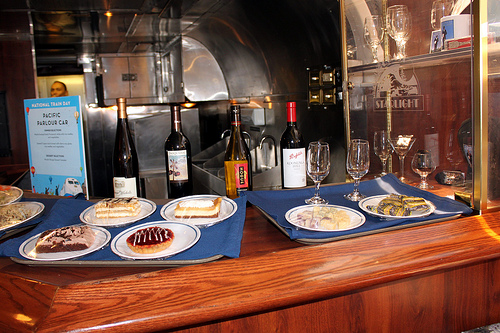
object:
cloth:
[197, 226, 245, 263]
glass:
[408, 147, 436, 188]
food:
[176, 197, 223, 217]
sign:
[16, 91, 95, 201]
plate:
[284, 202, 370, 234]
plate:
[109, 215, 201, 263]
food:
[127, 222, 174, 254]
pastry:
[179, 180, 219, 217]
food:
[34, 225, 94, 254]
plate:
[17, 223, 111, 262]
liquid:
[347, 160, 370, 177]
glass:
[299, 140, 330, 207]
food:
[376, 195, 424, 217]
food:
[299, 205, 346, 230]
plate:
[221, 200, 233, 217]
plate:
[345, 206, 361, 227]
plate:
[357, 194, 384, 210]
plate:
[26, 247, 92, 260]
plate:
[139, 197, 151, 217]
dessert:
[174, 193, 231, 228]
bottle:
[222, 102, 254, 198]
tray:
[11, 252, 223, 267]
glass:
[374, 130, 394, 177]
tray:
[243, 175, 468, 246]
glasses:
[295, 133, 411, 203]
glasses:
[280, 123, 375, 204]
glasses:
[373, 124, 450, 195]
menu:
[17, 92, 92, 199]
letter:
[374, 97, 386, 108]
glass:
[388, 116, 417, 180]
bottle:
[112, 95, 139, 197]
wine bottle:
[226, 97, 253, 201]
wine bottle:
[282, 100, 310, 187]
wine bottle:
[161, 100, 199, 196]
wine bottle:
[113, 100, 143, 183]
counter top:
[0, 174, 500, 330]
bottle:
[281, 103, 308, 191]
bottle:
[227, 105, 250, 194]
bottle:
[166, 104, 194, 194]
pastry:
[129, 223, 178, 258]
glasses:
[355, 4, 453, 68]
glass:
[330, 1, 493, 184]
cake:
[78, 177, 225, 288]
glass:
[343, 139, 370, 202]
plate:
[79, 197, 155, 227]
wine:
[108, 99, 140, 198]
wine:
[165, 103, 190, 199]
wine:
[223, 100, 251, 199]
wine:
[280, 100, 308, 189]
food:
[293, 207, 353, 230]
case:
[341, 0, 499, 211]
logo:
[374, 56, 423, 113]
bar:
[1, 189, 499, 331]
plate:
[156, 188, 238, 228]